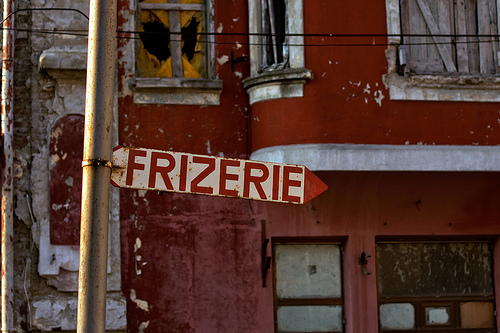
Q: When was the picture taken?
A: Daytime.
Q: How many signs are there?
A: One.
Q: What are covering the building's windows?
A: Boards.